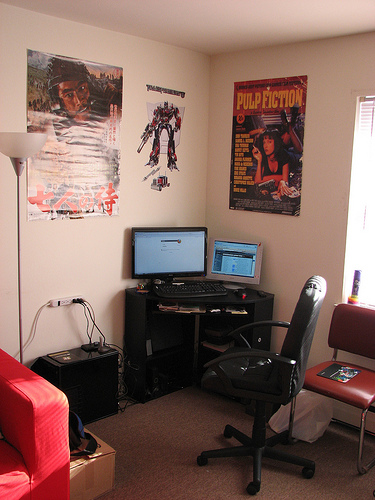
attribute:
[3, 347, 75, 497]
chair — plush, red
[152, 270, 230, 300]
keyboard — black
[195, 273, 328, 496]
chair — black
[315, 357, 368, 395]
chair — red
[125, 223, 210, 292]
monitor — on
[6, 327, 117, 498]
couch — red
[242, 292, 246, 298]
mouse — black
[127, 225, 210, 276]
monitor — on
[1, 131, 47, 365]
lamp — metal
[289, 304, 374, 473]
red chair — small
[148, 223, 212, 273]
monitor — on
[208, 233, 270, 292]
monitor — small